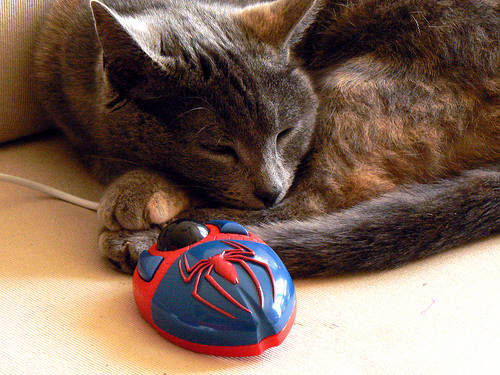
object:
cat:
[31, 0, 500, 281]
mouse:
[131, 219, 297, 358]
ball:
[154, 218, 211, 253]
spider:
[177, 239, 276, 320]